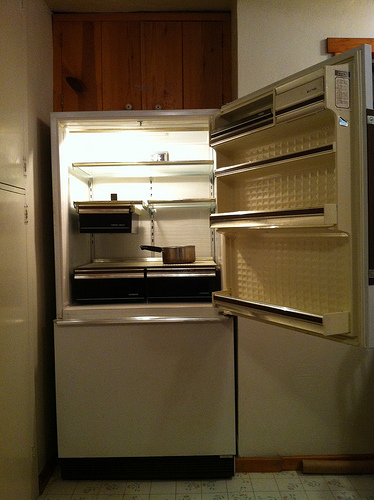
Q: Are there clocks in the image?
A: No, there are no clocks.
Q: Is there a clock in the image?
A: No, there are no clocks.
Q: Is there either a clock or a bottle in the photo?
A: No, there are no clocks or bottles.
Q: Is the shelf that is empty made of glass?
A: Yes, the shelf is made of glass.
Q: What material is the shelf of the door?
A: The shelf is made of glass.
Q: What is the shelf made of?
A: The shelf is made of glass.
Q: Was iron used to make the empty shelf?
A: No, the shelf is made of glass.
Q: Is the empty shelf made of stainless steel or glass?
A: The shelf is made of glass.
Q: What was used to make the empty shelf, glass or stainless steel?
A: The shelf is made of glass.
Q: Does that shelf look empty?
A: Yes, the shelf is empty.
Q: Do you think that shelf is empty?
A: Yes, the shelf is empty.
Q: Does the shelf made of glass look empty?
A: Yes, the shelf is empty.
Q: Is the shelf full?
A: No, the shelf is empty.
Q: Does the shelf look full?
A: No, the shelf is empty.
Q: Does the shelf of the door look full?
A: No, the shelf is empty.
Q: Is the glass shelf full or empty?
A: The shelf is empty.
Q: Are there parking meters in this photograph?
A: No, there are no parking meters.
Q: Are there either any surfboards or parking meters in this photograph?
A: No, there are no parking meters or surfboards.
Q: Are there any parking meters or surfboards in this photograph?
A: No, there are no parking meters or surfboards.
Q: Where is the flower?
A: The flower is on the floor.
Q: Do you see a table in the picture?
A: No, there are no tables.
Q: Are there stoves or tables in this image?
A: No, there are no tables or stoves.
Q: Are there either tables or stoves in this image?
A: No, there are no tables or stoves.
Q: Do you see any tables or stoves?
A: No, there are no tables or stoves.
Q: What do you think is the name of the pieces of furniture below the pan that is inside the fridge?
A: The pieces of furniture are drawers.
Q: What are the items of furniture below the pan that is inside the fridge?
A: The pieces of furniture are drawers.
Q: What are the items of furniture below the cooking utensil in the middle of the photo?
A: The pieces of furniture are drawers.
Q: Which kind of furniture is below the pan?
A: The pieces of furniture are drawers.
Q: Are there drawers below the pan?
A: Yes, there are drawers below the pan.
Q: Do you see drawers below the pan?
A: Yes, there are drawers below the pan.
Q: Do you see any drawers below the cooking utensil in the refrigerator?
A: Yes, there are drawers below the pan.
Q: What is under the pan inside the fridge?
A: The drawers are under the pan.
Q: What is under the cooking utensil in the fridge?
A: The drawers are under the pan.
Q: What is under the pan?
A: The drawers are under the pan.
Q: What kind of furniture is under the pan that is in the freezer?
A: The pieces of furniture are drawers.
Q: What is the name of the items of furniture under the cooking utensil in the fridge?
A: The pieces of furniture are drawers.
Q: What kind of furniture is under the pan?
A: The pieces of furniture are drawers.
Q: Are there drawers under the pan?
A: Yes, there are drawers under the pan.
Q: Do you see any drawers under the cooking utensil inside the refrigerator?
A: Yes, there are drawers under the pan.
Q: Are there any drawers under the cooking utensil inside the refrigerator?
A: Yes, there are drawers under the pan.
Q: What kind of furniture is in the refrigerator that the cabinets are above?
A: The pieces of furniture are drawers.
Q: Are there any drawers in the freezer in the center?
A: Yes, there are drawers in the refrigerator.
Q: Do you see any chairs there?
A: No, there are no chairs.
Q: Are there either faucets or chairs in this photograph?
A: No, there are no chairs or faucets.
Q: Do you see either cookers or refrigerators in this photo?
A: Yes, there is a refrigerator.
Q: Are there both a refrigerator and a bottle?
A: No, there is a refrigerator but no bottles.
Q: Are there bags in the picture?
A: No, there are no bags.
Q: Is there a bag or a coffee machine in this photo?
A: No, there are no bags or coffee makers.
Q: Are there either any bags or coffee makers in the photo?
A: No, there are no bags or coffee makers.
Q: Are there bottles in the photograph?
A: No, there are no bottles.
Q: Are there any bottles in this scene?
A: No, there are no bottles.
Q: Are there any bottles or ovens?
A: No, there are no bottles or ovens.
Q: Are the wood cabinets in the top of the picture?
A: Yes, the cabinets are in the top of the image.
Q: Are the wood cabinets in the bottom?
A: No, the cabinets are in the top of the image.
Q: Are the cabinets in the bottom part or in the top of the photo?
A: The cabinets are in the top of the image.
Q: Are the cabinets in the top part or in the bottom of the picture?
A: The cabinets are in the top of the image.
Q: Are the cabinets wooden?
A: Yes, the cabinets are wooden.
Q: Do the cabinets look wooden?
A: Yes, the cabinets are wooden.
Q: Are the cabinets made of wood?
A: Yes, the cabinets are made of wood.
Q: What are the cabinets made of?
A: The cabinets are made of wood.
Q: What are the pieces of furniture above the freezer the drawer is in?
A: The pieces of furniture are cabinets.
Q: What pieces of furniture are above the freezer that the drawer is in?
A: The pieces of furniture are cabinets.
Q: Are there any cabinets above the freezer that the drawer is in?
A: Yes, there are cabinets above the freezer.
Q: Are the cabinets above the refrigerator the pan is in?
A: Yes, the cabinets are above the fridge.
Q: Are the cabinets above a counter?
A: No, the cabinets are above the fridge.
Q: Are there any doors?
A: Yes, there is a door.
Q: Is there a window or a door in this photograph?
A: Yes, there is a door.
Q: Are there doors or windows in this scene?
A: Yes, there is a door.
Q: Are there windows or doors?
A: Yes, there is a door.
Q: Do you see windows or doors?
A: Yes, there is a door.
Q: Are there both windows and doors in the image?
A: No, there is a door but no windows.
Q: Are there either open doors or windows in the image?
A: Yes, there is an open door.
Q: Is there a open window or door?
A: Yes, there is an open door.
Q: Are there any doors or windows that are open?
A: Yes, the door is open.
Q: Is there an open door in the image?
A: Yes, there is an open door.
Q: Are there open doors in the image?
A: Yes, there is an open door.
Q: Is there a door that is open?
A: Yes, there is a door that is open.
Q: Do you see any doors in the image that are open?
A: Yes, there is a door that is open.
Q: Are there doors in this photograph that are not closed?
A: Yes, there is a open door.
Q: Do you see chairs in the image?
A: No, there are no chairs.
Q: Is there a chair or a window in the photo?
A: No, there are no chairs or windows.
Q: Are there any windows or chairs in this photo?
A: No, there are no chairs or windows.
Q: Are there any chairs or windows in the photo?
A: No, there are no chairs or windows.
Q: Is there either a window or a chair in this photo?
A: No, there are no chairs or windows.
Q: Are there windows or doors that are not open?
A: No, there is a door but it is open.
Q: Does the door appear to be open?
A: Yes, the door is open.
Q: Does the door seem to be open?
A: Yes, the door is open.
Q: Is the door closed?
A: No, the door is open.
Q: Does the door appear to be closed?
A: No, the door is open.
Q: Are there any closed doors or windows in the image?
A: No, there is a door but it is open.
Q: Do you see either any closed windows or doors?
A: No, there is a door but it is open.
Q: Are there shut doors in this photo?
A: No, there is a door but it is open.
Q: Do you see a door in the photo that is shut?
A: No, there is a door but it is open.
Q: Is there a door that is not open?
A: No, there is a door but it is open.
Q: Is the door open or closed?
A: The door is open.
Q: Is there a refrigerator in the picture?
A: Yes, there is a refrigerator.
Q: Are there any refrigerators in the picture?
A: Yes, there is a refrigerator.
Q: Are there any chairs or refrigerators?
A: Yes, there is a refrigerator.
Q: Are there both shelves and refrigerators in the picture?
A: Yes, there are both a refrigerator and a shelf.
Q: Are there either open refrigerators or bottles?
A: Yes, there is an open refrigerator.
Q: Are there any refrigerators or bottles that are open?
A: Yes, the refrigerator is open.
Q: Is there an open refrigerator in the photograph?
A: Yes, there is an open refrigerator.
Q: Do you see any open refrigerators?
A: Yes, there is an open refrigerator.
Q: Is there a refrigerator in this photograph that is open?
A: Yes, there is a refrigerator that is open.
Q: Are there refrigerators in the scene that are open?
A: Yes, there is a refrigerator that is open.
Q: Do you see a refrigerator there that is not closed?
A: Yes, there is a open refrigerator.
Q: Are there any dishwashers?
A: No, there are no dishwashers.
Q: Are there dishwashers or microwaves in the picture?
A: No, there are no dishwashers or microwaves.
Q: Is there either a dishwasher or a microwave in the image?
A: No, there are no dishwashers or microwaves.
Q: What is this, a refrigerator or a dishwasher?
A: This is a refrigerator.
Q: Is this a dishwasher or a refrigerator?
A: This is a refrigerator.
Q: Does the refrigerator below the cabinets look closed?
A: No, the fridge is open.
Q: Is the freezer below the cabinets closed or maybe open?
A: The fridge is open.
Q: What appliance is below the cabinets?
A: The appliance is a refrigerator.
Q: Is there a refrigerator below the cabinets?
A: Yes, there is a refrigerator below the cabinets.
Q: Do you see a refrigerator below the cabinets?
A: Yes, there is a refrigerator below the cabinets.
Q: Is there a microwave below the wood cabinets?
A: No, there is a refrigerator below the cabinets.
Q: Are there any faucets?
A: No, there are no faucets.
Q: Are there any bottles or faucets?
A: No, there are no faucets or bottles.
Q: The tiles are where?
A: The tiles are on the floor.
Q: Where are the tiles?
A: The tiles are on the floor.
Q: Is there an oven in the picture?
A: No, there are no ovens.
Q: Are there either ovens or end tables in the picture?
A: No, there are no ovens or end tables.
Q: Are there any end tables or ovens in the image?
A: No, there are no ovens or end tables.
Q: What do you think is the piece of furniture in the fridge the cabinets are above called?
A: The piece of furniture is a drawer.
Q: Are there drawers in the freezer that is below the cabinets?
A: Yes, there is a drawer in the refrigerator.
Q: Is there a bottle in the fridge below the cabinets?
A: No, there is a drawer in the refrigerator.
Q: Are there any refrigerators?
A: Yes, there is a refrigerator.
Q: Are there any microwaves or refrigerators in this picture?
A: Yes, there is a refrigerator.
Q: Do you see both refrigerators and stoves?
A: No, there is a refrigerator but no stoves.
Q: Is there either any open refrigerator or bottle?
A: Yes, there is an open refrigerator.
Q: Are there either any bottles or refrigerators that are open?
A: Yes, the refrigerator is open.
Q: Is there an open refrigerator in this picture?
A: Yes, there is an open refrigerator.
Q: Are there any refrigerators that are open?
A: Yes, there is a refrigerator that is open.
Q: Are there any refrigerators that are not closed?
A: Yes, there is a open refrigerator.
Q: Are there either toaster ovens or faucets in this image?
A: No, there are no faucets or toaster ovens.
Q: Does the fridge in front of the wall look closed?
A: No, the freezer is open.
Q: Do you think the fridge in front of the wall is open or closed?
A: The fridge is open.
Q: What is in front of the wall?
A: The fridge is in front of the wall.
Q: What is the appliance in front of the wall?
A: The appliance is a refrigerator.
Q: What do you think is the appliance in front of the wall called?
A: The appliance is a refrigerator.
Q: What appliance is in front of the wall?
A: The appliance is a refrigerator.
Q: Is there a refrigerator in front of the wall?
A: Yes, there is a refrigerator in front of the wall.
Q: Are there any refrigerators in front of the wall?
A: Yes, there is a refrigerator in front of the wall.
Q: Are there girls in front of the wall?
A: No, there is a refrigerator in front of the wall.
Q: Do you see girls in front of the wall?
A: No, there is a refrigerator in front of the wall.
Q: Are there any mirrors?
A: No, there are no mirrors.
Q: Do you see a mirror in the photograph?
A: No, there are no mirrors.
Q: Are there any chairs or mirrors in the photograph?
A: No, there are no mirrors or chairs.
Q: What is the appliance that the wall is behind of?
A: The appliance is a refrigerator.